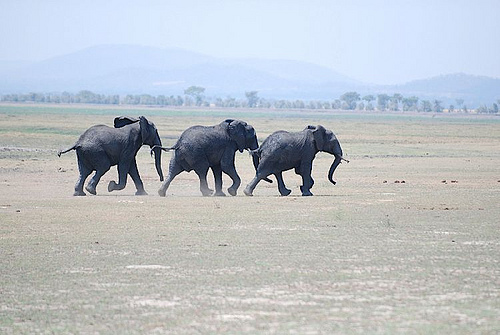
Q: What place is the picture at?
A: It is at the plain.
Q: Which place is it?
A: It is a plain.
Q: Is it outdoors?
A: Yes, it is outdoors.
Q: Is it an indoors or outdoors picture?
A: It is outdoors.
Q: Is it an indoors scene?
A: No, it is outdoors.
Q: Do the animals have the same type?
A: Yes, all the animals are elephants.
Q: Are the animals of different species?
A: No, all the animals are elephants.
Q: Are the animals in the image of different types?
A: No, all the animals are elephants.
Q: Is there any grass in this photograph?
A: Yes, there is grass.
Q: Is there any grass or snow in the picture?
A: Yes, there is grass.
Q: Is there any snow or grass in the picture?
A: Yes, there is grass.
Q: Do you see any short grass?
A: Yes, there is short grass.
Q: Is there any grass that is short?
A: Yes, there is grass that is short.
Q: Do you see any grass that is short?
A: Yes, there is grass that is short.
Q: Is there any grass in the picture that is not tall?
A: Yes, there is short grass.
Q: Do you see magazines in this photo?
A: No, there are no magazines.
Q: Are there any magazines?
A: No, there are no magazines.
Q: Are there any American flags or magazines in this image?
A: No, there are no magazines or American flags.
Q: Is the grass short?
A: Yes, the grass is short.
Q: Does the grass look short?
A: Yes, the grass is short.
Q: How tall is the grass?
A: The grass is short.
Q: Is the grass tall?
A: No, the grass is short.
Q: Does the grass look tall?
A: No, the grass is short.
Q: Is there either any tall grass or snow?
A: No, there is grass but it is short.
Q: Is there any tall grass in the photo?
A: No, there is grass but it is short.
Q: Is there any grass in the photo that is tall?
A: No, there is grass but it is short.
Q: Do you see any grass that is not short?
A: No, there is grass but it is short.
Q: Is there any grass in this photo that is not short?
A: No, there is grass but it is short.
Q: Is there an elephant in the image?
A: Yes, there is an elephant.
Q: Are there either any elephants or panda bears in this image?
A: Yes, there is an elephant.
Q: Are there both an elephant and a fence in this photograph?
A: No, there is an elephant but no fences.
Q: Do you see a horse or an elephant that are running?
A: Yes, the elephant is running.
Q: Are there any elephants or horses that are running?
A: Yes, the elephant is running.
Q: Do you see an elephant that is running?
A: Yes, there is an elephant that is running.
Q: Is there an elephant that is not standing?
A: Yes, there is an elephant that is running.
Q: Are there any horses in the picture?
A: No, there are no horses.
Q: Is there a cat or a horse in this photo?
A: No, there are no horses or cats.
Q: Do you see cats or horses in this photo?
A: No, there are no horses or cats.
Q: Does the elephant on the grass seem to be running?
A: Yes, the elephant is running.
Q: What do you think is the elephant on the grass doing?
A: The elephant is running.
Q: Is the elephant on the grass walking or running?
A: The elephant is running.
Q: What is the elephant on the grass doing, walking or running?
A: The elephant is running.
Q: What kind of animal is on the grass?
A: The animal is an elephant.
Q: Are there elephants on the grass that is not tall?
A: Yes, there is an elephant on the grass.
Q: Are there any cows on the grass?
A: No, there is an elephant on the grass.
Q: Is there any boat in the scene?
A: No, there are no boats.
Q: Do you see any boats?
A: No, there are no boats.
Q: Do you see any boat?
A: No, there are no boats.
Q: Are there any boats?
A: No, there are no boats.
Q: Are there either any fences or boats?
A: No, there are no boats or fences.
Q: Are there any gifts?
A: No, there are no gifts.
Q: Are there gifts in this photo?
A: No, there are no gifts.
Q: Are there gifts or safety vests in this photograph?
A: No, there are no gifts or safety vests.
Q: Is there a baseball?
A: No, there are no baseballs.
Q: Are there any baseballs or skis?
A: No, there are no baseballs or skis.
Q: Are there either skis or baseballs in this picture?
A: No, there are no baseballs or skis.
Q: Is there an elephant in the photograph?
A: Yes, there is an elephant.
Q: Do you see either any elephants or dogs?
A: Yes, there is an elephant.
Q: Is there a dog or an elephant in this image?
A: Yes, there is an elephant.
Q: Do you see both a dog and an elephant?
A: No, there is an elephant but no dogs.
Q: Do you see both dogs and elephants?
A: No, there is an elephant but no dogs.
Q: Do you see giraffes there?
A: No, there are no giraffes.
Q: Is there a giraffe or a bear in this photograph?
A: No, there are no giraffes or bears.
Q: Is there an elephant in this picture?
A: Yes, there is an elephant.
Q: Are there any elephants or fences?
A: Yes, there is an elephant.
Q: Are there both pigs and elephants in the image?
A: No, there is an elephant but no pigs.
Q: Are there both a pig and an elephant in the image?
A: No, there is an elephant but no pigs.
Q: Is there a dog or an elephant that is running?
A: Yes, the elephant is running.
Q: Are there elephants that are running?
A: Yes, there is an elephant that is running.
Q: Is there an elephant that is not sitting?
A: Yes, there is an elephant that is running.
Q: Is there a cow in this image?
A: No, there are no cows.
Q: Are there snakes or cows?
A: No, there are no cows or snakes.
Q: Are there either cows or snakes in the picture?
A: No, there are no cows or snakes.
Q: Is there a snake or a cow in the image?
A: No, there are no cows or snakes.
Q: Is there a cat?
A: No, there are no cats.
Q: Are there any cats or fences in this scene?
A: No, there are no cats or fences.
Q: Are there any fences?
A: No, there are no fences.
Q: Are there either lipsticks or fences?
A: No, there are no fences or lipsticks.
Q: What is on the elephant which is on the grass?
A: The trunk is on the elephant.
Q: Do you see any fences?
A: No, there are no fences.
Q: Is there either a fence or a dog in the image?
A: No, there are no fences or dogs.